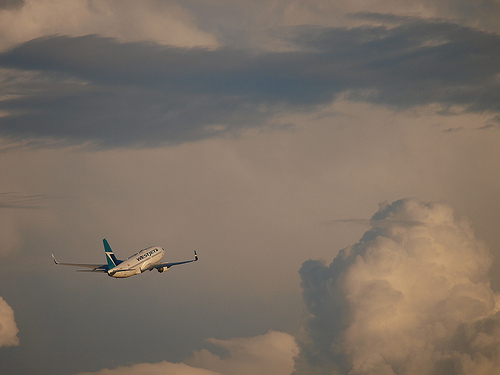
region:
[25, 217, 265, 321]
The plane is white.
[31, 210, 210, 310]
Tail fin is blue.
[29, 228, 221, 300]
Lettering on side of plane.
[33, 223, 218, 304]
The lettering is blue.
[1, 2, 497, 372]
The sky is cloudy.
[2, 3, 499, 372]
The sky is darkened.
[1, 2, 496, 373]
The sky is ominous.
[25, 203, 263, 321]
The plane is airborne.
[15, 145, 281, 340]
The plane is in flight.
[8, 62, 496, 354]
The plane is alone.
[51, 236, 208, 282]
the plane is in the air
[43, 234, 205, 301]
the plane is silver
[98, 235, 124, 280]
the plane has a tail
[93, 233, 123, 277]
the tail of the plane is blue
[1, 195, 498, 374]
the sky is full of clouds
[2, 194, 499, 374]
the clouds are big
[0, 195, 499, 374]
the clouds are fluffy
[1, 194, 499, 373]
the clouds are puffy and white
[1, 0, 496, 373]
the sky is grey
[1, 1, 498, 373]
the sky is hazy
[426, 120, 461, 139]
cirrus cloud in sky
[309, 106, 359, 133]
cirrus cloud in sky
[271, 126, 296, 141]
cirrus cloud in sky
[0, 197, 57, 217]
cirrus cloud in sky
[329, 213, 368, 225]
cirrus cloud in sky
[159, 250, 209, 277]
right wing of airplane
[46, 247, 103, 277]
left wing of airplane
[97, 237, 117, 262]
tail of white airplane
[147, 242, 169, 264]
nose of white airplane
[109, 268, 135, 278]
side of white airplane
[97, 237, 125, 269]
The fin of the plane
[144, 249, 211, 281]
The wing of the airplane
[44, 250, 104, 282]
The wing is white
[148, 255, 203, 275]
The blue part of the wing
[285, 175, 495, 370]
Clouds in the sky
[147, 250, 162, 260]
Windows on the plane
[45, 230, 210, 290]
The white airplane flies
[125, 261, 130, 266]
A red mark on the plane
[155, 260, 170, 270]
The white wind turbine motor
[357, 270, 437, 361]
The cloud is white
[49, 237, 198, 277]
a commercial passenger plane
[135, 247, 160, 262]
the name of the airline on the side of the jet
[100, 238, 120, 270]
the green and black tail of the jet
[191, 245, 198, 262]
the wings wing tip reduces drag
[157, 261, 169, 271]
the jets turbine engine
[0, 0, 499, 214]
blue sky with many clouds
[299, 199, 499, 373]
a puffy white cloud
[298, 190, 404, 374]
a shadow on the backside of the cloud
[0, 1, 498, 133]
high clouds above the jet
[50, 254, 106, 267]
the jets port side wing